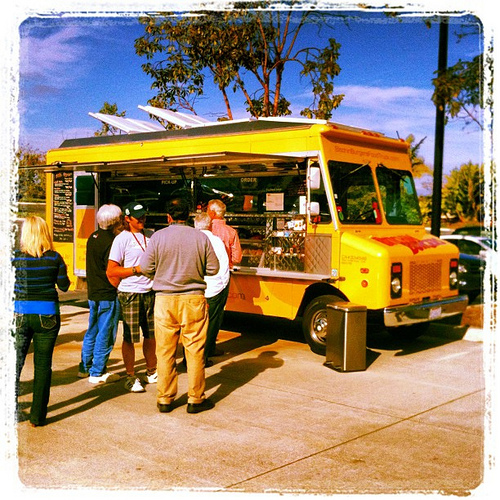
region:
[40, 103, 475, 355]
yellow food truck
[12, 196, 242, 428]
people standing in line at the food truck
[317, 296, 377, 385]
trash can by food truck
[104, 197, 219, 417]
two men talking in line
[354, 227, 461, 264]
red title on yellow food truck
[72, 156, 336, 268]
food truck is open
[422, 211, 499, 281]
cars parked in the background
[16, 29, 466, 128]
blue sky with a few clouds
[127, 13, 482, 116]
trees behind the food truck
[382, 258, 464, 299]
headlights of food truck are off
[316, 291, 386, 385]
metal trash can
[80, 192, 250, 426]
group of five people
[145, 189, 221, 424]
back of man wearing yellow pants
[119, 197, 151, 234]
green baseball cap on man's head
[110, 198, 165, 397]
man wearing plaid shorts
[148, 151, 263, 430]
people waiting in line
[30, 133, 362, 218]
open awning of food truck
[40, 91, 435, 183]
open top vents on yellow truck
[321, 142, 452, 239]
vehicle windshield with fire extinguisher inside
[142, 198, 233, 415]
Man in a gray shirt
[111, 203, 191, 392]
Man in a white shirt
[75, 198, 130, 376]
Man in a black shirt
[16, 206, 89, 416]
Woman with blonde hair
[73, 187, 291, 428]
Men standing next to a truck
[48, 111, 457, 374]
Yellow truck parked on a lot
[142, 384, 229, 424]
Black shoes on a man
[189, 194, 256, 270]
Pink shirt on a man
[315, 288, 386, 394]
Silver trash can by a van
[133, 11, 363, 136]
Tree behind a truck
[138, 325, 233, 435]
Person wearing tan pants.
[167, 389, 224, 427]
Person wearing dark shoes.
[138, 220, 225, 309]
Person wearing gray sweater.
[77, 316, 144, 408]
Person wearing blue jeans.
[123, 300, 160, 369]
Person wearing plaid shorts.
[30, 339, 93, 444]
Person wearing dark pants.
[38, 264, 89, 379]
Person wearing blue and black sweater.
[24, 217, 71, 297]
Person has blonde hair.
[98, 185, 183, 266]
Person wearing black hat.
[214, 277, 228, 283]
Person wearing white shirt.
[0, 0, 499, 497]
slightly stylized image of people standing near a food truck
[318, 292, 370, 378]
metal rubbish bin on the ground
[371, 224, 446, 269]
red text on front of truck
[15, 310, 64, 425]
woman wearing tight fitting jeans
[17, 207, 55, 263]
woman with blonde hair falling on her shoulders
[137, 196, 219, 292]
man wearing a grey long-sleeved shirt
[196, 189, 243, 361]
man standing directly in front of truck and looking to his left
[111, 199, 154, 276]
woman wearing a red lanyard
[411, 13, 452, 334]
black pole behind food truck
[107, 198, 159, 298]
woman wearing a white shirt